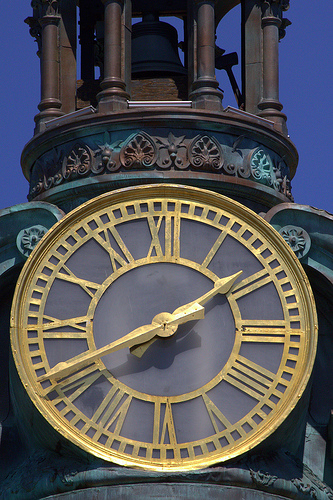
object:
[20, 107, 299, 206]
copper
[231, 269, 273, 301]
numeral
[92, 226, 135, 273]
eleven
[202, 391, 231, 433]
numeral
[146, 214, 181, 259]
numeral twelve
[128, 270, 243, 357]
hand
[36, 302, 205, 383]
hand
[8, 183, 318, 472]
clock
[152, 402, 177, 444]
number six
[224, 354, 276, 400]
roman numeral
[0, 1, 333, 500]
bell tower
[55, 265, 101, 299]
x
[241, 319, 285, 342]
roman numeral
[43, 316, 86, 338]
roman numeral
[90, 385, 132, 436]
roman numeral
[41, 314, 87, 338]
nine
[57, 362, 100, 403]
numeral eight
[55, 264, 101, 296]
roman numeral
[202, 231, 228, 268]
roman numeral